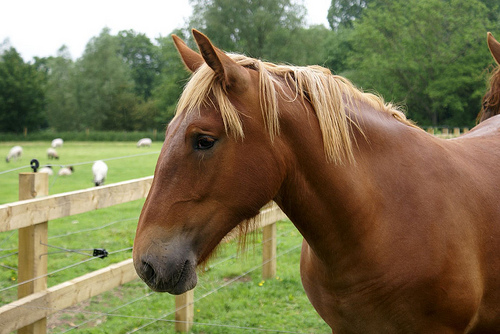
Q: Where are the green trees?
A: In the distance.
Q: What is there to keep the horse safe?
A: Wooden fence.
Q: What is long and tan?
A: The mane of the horse.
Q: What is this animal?
A: Horse.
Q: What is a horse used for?
A: Riding.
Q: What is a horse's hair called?
A: Mane.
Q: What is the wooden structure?
A: Fence.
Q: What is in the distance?
A: Trees.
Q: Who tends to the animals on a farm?
A: Farmer.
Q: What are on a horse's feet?
A: Horseshoes.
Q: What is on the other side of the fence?
A: Sheep.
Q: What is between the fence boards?
A: Wire.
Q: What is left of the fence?
A: Animals grazing.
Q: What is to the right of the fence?
A: A horse.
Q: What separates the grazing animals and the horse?
A: A fence.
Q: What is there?
A: Animals.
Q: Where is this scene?
A: Farm.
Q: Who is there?
A: No one.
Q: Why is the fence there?
A: Separate.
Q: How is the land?
A: Grassland.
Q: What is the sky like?
A: Overcast.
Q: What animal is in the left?
A: Sheep.